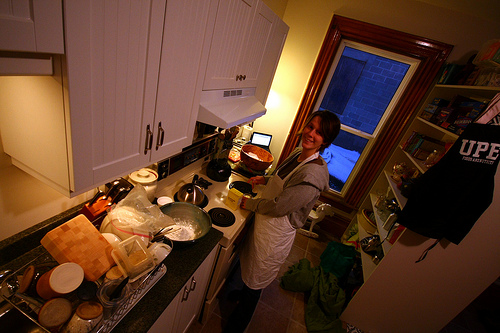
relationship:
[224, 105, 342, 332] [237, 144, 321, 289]
woman wears apron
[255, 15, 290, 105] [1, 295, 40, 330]
cabinet over sink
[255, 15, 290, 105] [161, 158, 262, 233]
cabinet over stove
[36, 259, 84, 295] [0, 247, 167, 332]
dish in dish drainer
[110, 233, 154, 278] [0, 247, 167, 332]
dish in dish drainer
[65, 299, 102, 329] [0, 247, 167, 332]
dish in dish drainer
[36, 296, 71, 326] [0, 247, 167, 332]
dish in dish drainer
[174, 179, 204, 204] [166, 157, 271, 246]
kettle on stove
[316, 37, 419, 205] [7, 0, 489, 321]
door in kitchen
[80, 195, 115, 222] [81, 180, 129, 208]
block with knives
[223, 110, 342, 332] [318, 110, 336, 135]
woman with hair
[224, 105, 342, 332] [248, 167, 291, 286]
woman in an apron